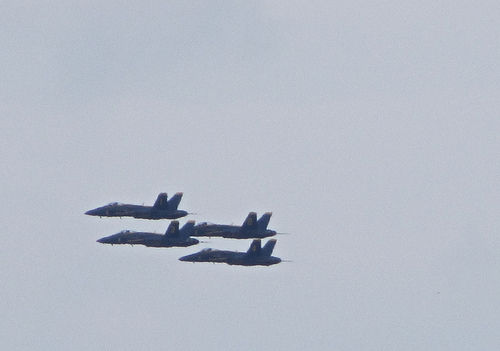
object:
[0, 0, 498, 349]
sky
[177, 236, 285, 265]
planes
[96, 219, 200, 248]
blue angels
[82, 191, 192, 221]
pilots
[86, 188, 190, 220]
airplanes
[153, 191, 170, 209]
wings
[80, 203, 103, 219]
nose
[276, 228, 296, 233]
steam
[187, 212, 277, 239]
plane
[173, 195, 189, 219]
end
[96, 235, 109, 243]
front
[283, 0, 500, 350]
air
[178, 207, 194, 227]
back